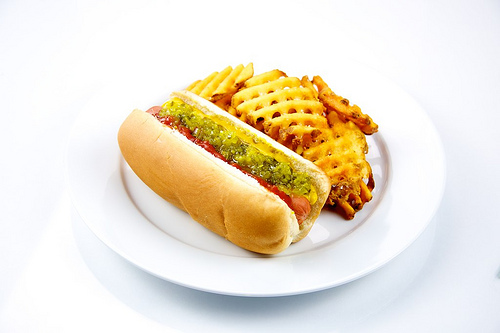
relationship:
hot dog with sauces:
[149, 105, 311, 223] [167, 101, 313, 204]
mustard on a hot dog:
[171, 99, 283, 158] [117, 89, 330, 256]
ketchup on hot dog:
[165, 118, 290, 206] [149, 105, 311, 223]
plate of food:
[81, 58, 446, 300] [120, 62, 380, 256]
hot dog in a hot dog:
[149, 105, 311, 223] [117, 89, 330, 256]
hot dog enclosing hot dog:
[117, 89, 330, 256] [149, 105, 311, 223]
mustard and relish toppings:
[171, 99, 283, 158] [182, 117, 288, 187]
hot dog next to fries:
[117, 89, 330, 256] [188, 65, 378, 219]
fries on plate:
[188, 65, 378, 219] [81, 58, 446, 300]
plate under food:
[81, 58, 446, 300] [120, 62, 380, 256]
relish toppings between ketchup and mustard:
[182, 117, 288, 187] [171, 99, 283, 158]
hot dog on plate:
[117, 89, 330, 256] [81, 58, 446, 300]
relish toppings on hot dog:
[182, 117, 288, 187] [117, 89, 330, 256]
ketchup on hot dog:
[165, 118, 290, 206] [117, 89, 330, 256]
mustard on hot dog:
[171, 99, 283, 158] [117, 89, 330, 256]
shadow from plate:
[155, 294, 351, 319] [81, 58, 446, 300]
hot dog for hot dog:
[117, 89, 330, 256] [149, 105, 311, 223]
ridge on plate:
[116, 133, 397, 256] [81, 58, 446, 300]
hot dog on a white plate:
[117, 89, 330, 256] [81, 58, 446, 300]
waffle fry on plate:
[232, 77, 323, 147] [81, 58, 446, 300]